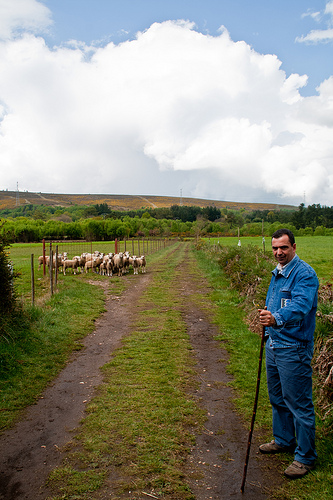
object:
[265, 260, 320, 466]
outfit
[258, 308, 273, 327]
fist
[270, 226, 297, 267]
head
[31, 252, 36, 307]
fence post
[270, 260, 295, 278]
collar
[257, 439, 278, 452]
shoe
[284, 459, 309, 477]
shoe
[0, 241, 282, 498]
dirt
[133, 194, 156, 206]
road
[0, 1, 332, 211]
clouds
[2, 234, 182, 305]
fence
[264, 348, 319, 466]
pants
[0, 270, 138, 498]
rut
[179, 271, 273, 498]
rut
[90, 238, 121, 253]
gate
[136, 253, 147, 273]
animals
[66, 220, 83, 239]
tree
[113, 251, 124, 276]
sheep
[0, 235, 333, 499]
grass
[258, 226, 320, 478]
man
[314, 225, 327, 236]
trees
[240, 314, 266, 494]
stick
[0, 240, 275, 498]
path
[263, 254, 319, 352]
clothing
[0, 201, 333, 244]
forest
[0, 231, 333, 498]
field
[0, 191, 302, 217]
hill